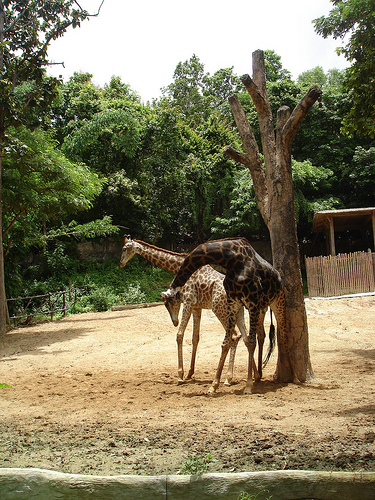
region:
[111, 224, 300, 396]
TWO YOUNG GIRAFFES ON DISPLAY AT ZOO.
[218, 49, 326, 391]
DEAD TREE THAT HAS BEEN EATEN BY GIRAFFES.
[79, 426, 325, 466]
MUDDY GROUND INSIDE GIRAFFE DISPLAY.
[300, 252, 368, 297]
SMALL FENCE INSIDE GIRAFFE DISPLAY.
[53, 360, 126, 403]
DRY SAND INSIDE GIRAFFE DISPLAY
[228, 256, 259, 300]
DARK GIRAFFE PATTERN ON YOUNG GIRAFFE.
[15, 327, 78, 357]
SHADOWS FROM TREES INSIDE GIRAFFE DISPLAY.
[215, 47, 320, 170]
CUT TREE BRANCHES ON DEAD TREE.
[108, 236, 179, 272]
LONG GIRAFFE NECK.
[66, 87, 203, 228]
LUSH GREEN LEAVES ON TALL TREES.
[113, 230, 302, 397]
Two giraffes standing in sand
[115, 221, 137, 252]
Horns on a giraffe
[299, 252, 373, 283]
Wooden fence in background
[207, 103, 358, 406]
Tree growing out of sand and dirt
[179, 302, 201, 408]
Legs of a giraffe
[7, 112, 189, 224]
Green leaves in background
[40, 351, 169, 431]
Sand and dirt on ground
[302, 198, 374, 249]
Open air shelter cover from sun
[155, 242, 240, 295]
Neck of a dark giraffe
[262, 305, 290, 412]
Tail of a giraffe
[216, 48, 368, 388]
large tree next to giraffs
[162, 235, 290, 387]
dark brown giraffe next to tree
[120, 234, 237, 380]
light brown giraffe next to tree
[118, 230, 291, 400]
two giraffes standing next to each other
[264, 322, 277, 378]
bushy tail connected to dark brown giraffe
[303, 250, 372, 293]
fence behind giraffes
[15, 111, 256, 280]
trees and bushes behind giraffes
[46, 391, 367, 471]
brown dirt giraffes stand on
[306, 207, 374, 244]
small hut behind giraffes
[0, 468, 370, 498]
short concrete wall in front of giraffes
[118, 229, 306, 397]
Two giraffes next a tree.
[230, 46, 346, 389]
A tree without leaves.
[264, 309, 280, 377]
A tail of a giraffe.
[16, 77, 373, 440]
A zoo that have giraffes.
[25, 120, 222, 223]
Trees Around the pen of giraffes.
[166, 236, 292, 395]
A giraffe with the neck down.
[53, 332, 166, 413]
Soil without grass.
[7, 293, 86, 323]
A fence in the zoo.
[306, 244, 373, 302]
A small fence behind two giraffes.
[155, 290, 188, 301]
Two ears of a giraffe.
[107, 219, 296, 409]
two giraffes near a tree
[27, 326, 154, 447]
an open dirt area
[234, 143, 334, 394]
a tree trunk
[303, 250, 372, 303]
a wooden fence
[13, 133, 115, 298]
trees with green leaves in the background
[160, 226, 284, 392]
a dark colored giraffe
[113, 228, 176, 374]
a light colored giraffe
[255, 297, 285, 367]
the dark giraffe's tail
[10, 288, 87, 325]
a small dark fence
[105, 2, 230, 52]
the sky